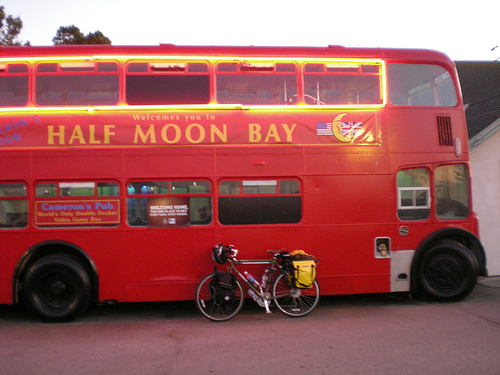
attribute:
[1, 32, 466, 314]
bus — red, yellow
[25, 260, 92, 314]
tire — shiny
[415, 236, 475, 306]
tire — shiny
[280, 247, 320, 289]
bag — yellow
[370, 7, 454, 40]
sky — blue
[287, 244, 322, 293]
bag — yellow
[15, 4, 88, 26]
clouds — white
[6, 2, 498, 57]
sky — blue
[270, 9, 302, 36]
clouds — white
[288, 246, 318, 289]
bag — yellow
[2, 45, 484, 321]
bus — yellow, red, red and yellow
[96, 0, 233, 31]
clouds — white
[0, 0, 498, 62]
clouds — white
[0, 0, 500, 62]
sky — blue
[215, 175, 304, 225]
window — open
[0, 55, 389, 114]
light — neon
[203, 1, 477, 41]
sky — blue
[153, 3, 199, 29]
clouds — white